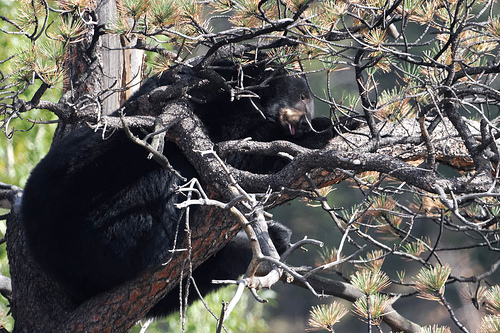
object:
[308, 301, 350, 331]
flower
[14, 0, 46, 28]
leaves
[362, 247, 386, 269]
leaves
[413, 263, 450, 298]
leaves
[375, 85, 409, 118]
leaves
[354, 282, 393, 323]
growth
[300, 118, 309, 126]
nose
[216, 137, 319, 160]
stem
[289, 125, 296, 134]
red tongue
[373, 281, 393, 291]
needles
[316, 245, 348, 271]
flowers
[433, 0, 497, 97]
twigs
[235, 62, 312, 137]
head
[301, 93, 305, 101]
eye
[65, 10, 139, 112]
stem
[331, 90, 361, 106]
leaves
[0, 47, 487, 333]
bark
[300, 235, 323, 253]
sprig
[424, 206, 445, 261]
sprig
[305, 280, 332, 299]
sprig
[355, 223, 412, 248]
sprig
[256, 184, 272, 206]
sprig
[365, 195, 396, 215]
bunch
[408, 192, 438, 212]
leaves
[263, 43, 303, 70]
leaves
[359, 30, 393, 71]
leaves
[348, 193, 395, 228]
leaves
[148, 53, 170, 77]
leaves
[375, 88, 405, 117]
leaves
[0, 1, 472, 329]
growth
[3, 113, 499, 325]
branch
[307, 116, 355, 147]
leg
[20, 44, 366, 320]
animal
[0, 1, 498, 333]
tree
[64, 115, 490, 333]
branch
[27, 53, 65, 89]
leaves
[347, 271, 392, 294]
leaves